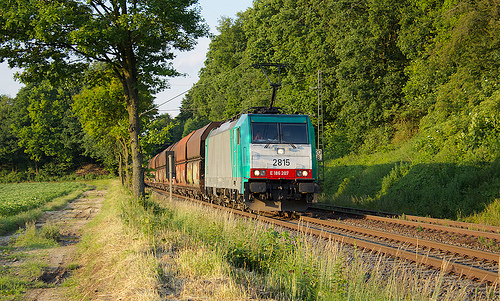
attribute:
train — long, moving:
[144, 107, 317, 214]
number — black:
[271, 156, 278, 169]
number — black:
[275, 157, 284, 168]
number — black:
[281, 157, 288, 166]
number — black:
[284, 157, 292, 167]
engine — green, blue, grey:
[232, 111, 320, 211]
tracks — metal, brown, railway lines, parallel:
[153, 182, 499, 285]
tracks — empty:
[306, 198, 499, 242]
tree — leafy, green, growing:
[6, 0, 205, 214]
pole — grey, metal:
[168, 153, 176, 205]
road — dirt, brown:
[5, 181, 107, 300]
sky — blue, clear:
[3, 2, 255, 117]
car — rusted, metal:
[184, 120, 224, 197]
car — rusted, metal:
[172, 129, 194, 194]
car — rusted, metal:
[157, 142, 170, 192]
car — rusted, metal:
[151, 152, 160, 189]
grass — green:
[313, 126, 498, 228]